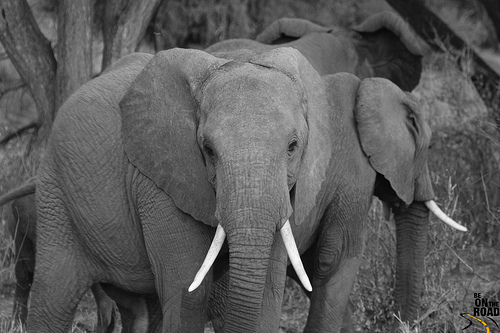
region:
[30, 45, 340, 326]
Large elephant standing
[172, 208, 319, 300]
Tusks of an elephant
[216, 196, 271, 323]
Trunk of an elephant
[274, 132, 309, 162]
The eye of an elephant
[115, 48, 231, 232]
One ear of an elephant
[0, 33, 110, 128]
Trees behind an elephant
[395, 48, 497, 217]
Large rock behind an elephant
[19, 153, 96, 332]
Rear leg of an elephant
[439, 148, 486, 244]
Tall grass behind elephants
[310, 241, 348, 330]
Front leg of an elephant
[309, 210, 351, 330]
Leg of an elephant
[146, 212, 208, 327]
Leg of an elephant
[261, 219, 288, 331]
Leg of an elephant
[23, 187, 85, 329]
Leg of an elephant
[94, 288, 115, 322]
Leg of an elephant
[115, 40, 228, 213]
Ear of an elephant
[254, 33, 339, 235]
Ear of an elephant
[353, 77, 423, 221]
Ear of an elephant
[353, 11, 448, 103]
Ear of an elephant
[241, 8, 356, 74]
Ear of an elephant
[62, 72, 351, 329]
elephant is looking forward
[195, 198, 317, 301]
elephant has two long tusks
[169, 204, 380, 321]
elephant's tusks are white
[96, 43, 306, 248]
elephant has large ears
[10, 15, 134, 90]
tree trunks behind elephant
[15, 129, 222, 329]
elephant has large legs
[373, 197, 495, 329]
thick reeds behind elephant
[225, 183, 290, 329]
elephant has wide trunk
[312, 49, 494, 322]
second elephant is looking right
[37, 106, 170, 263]
elephant has wrinkled skin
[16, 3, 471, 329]
There are three elephants.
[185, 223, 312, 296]
The elephant has white tusks.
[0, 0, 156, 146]
A tree trunk behind the elephants.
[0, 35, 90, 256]
Stones behind the tree.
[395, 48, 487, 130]
There is a stone on the ground.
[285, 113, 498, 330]
There is grass on the ground.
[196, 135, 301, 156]
The elephant has black eyes.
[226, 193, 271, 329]
Ridges on the elephant's trunk.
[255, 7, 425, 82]
The back side of an elephant's head.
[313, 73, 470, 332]
An elephant standing between two elephants.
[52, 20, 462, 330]
a herd of elephants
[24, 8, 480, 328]
a herd of African elephants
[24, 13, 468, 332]
African elephants standing around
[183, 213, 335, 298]
white tusks of an elephant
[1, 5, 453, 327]
elephants standing among the trees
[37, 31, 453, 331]
elephants in the wild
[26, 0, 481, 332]
African elephants in the wild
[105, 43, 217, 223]
an African elephant's ear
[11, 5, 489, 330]
elephants standing in the bush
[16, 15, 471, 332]
a herd of elephants among the brush